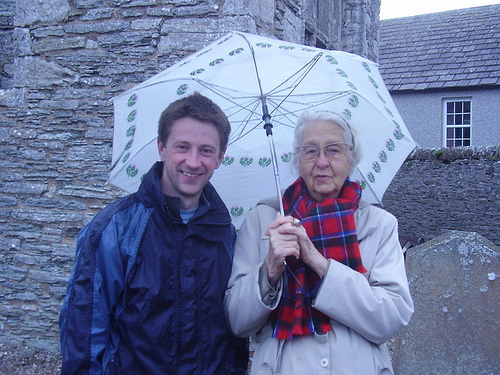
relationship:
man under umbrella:
[58, 90, 251, 375] [104, 30, 418, 233]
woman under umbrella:
[222, 106, 414, 374] [104, 30, 418, 233]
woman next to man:
[222, 106, 414, 374] [58, 90, 251, 375]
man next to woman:
[58, 90, 251, 375] [222, 106, 414, 374]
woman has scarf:
[222, 106, 414, 374] [268, 176, 367, 340]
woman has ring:
[222, 106, 414, 374] [293, 218, 302, 227]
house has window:
[376, 2, 499, 154] [440, 95, 473, 147]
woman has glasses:
[222, 106, 414, 374] [293, 141, 348, 162]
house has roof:
[376, 2, 499, 154] [376, 3, 499, 93]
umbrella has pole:
[104, 30, 418, 233] [260, 98, 285, 226]